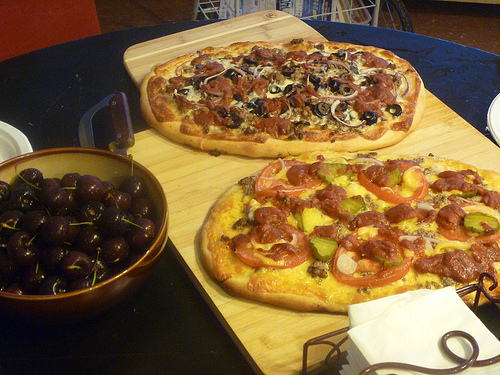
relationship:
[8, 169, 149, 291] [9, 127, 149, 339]
fruit in a bowl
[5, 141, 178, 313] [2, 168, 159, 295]
bowl of cherries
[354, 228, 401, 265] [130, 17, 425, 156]
red topping on pizza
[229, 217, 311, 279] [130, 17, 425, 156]
tomato on pizza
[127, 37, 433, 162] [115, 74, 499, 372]
pizza on a board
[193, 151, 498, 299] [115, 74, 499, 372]
pizza on a board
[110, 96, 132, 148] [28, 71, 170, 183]
handle on a pizza cutter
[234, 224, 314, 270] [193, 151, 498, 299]
tomato on a pizza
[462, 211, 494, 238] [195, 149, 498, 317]
pickle on a pizza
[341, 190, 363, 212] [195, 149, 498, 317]
pickle on a pizza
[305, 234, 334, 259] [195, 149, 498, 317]
pickle on a pizza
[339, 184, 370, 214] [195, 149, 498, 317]
pickle on a pizza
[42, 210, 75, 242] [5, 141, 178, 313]
cherry in a bowl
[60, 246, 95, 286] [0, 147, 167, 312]
cherry in a bowl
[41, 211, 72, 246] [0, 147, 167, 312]
cherry in a bowl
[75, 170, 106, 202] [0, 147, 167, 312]
cherry in a bowl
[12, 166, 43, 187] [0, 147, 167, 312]
cherry in a bowl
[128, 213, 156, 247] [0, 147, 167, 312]
cherry in a bowl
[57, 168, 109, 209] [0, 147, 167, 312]
cherry in a bowl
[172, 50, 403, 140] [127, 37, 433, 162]
meat on pizza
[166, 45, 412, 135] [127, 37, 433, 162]
onion on pizza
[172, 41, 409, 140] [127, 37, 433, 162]
black olives on pizza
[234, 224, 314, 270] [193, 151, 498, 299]
tomato on pizza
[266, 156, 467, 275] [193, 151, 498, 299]
cheese on pizza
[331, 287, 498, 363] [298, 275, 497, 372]
paper napkins on a rack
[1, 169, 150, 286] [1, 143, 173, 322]
cherries in a bowl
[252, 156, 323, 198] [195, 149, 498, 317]
tomato on pizza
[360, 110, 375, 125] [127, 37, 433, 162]
olive on pizza